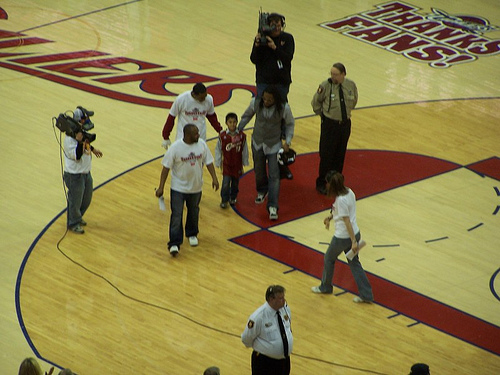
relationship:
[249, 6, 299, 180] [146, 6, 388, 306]
camerman filming scene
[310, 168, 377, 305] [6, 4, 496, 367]
woman on court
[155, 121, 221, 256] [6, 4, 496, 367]
man walking court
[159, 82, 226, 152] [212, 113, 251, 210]
man walking with boy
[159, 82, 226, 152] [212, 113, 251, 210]
man walking boy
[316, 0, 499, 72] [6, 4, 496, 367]
writing on court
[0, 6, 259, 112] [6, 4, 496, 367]
logo on court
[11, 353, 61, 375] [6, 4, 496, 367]
woman watching court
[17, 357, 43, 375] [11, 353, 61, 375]
head of a woman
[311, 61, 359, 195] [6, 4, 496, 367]
officer on court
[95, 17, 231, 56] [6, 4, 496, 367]
part of a court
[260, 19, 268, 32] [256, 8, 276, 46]
part of a camera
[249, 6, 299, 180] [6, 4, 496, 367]
camerman on court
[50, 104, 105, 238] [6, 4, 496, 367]
camerman on court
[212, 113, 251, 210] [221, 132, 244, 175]
boy in red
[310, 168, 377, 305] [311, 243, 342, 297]
woman has a left leg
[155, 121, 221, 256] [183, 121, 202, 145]
man has a head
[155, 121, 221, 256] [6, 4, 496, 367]
man on court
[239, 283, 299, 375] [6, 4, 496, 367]
security on court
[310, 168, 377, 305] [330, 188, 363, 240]
woman in a shirt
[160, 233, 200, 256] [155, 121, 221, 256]
shoes on a man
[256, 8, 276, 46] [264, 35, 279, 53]
camera in hand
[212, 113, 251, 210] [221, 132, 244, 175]
boy wearing jersey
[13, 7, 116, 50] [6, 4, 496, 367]
three point line on court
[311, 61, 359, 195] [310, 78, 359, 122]
officer with shirt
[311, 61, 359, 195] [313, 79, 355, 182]
man in uniform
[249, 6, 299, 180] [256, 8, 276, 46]
camerman holding camera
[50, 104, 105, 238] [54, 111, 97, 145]
camerman hollding camera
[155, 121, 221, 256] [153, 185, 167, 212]
man carrying paper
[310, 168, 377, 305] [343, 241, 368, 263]
woman carrying paper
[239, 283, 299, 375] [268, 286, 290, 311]
security wearing headphone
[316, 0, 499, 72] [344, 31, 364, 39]
writing with frame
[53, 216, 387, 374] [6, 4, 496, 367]
cord on court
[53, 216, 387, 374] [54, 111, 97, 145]
cord from camera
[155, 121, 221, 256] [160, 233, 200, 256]
man wearing shoes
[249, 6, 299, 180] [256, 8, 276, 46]
camerman looking through camera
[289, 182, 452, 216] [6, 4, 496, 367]
line on court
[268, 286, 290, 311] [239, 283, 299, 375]
headphone on security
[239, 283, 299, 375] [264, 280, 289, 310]
security has head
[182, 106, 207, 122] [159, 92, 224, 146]
symbol on shirt